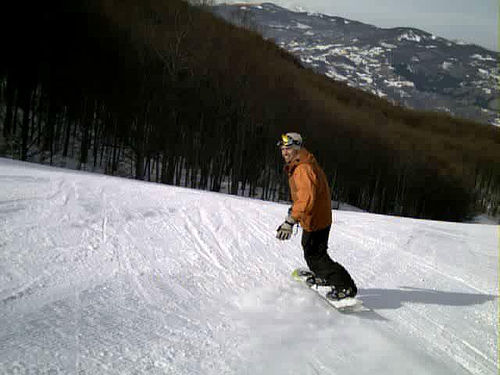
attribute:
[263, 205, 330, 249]
hand — man's, gloved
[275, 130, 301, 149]
cap — knit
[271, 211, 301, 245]
gloves — grey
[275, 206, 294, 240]
glove — gray, black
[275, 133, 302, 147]
goggles — ski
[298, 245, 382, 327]
snowboard — white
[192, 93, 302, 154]
wall — black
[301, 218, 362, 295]
pants — black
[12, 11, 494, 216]
trees — line, bare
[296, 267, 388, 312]
boot — snow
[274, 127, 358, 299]
man — snowboarding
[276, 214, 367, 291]
pants — black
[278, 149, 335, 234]
jacket — orange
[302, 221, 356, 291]
pants — black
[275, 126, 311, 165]
hat — white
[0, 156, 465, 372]
patches — snow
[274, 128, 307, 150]
goggles — snow, yellow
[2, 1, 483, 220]
side — mountain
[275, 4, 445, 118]
patches — snow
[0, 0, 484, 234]
trees — wide, expanse, tall , brown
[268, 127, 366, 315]
man — snowboarding